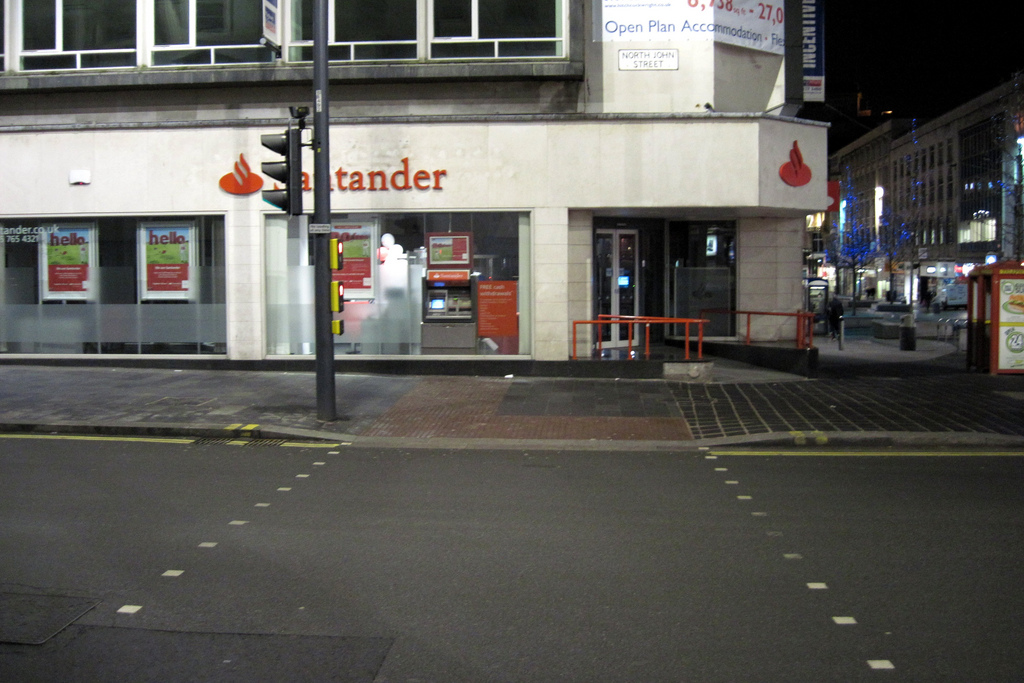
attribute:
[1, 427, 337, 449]
line — yellow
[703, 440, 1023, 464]
line — yellow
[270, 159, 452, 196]
letters — red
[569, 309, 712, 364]
railing — red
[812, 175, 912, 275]
lights — blue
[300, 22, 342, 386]
pole — tall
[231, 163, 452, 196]
logo — orange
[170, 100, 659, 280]
background — white